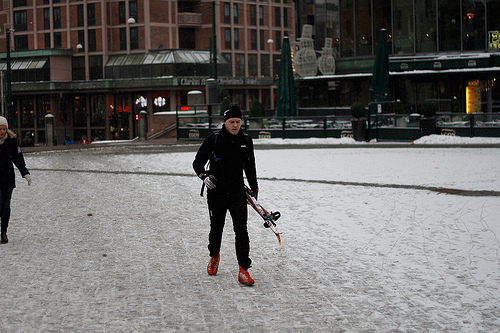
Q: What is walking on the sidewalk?
A: The man.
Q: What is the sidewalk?
A: Light grey.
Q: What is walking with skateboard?
A: The person.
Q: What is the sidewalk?
A: Light grey.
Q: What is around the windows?
A: White frame.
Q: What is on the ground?
A: The snow.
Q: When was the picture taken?
A: Daytime.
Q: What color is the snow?
A: White.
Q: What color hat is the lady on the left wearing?
A: White.